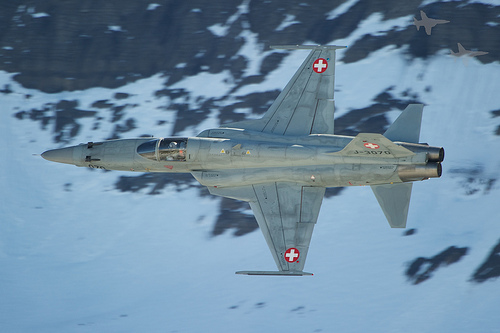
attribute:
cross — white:
[311, 54, 329, 75]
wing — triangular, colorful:
[263, 41, 348, 133]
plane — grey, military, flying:
[40, 45, 444, 278]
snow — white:
[0, 193, 205, 328]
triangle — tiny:
[219, 147, 226, 154]